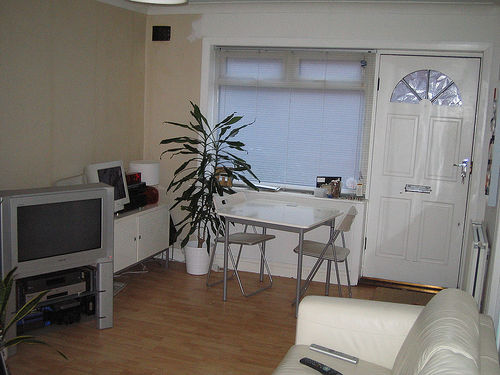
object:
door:
[360, 53, 483, 296]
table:
[215, 196, 345, 320]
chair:
[295, 205, 361, 298]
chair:
[205, 192, 275, 299]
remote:
[298, 355, 342, 375]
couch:
[269, 289, 500, 375]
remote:
[310, 342, 358, 363]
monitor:
[54, 158, 131, 215]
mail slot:
[401, 182, 432, 196]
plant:
[155, 100, 263, 255]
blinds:
[212, 47, 366, 195]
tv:
[1, 182, 114, 281]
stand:
[1, 260, 118, 344]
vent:
[459, 220, 490, 313]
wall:
[475, 0, 499, 312]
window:
[388, 69, 462, 107]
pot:
[181, 238, 213, 274]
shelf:
[110, 204, 170, 273]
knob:
[450, 157, 472, 185]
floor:
[1, 259, 448, 372]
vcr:
[25, 268, 84, 291]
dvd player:
[23, 283, 86, 306]